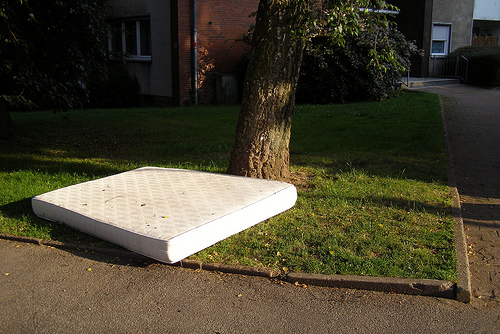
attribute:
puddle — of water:
[404, 50, 461, 95]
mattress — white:
[24, 159, 299, 269]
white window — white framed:
[427, 20, 452, 60]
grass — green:
[265, 218, 312, 256]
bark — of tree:
[227, 1, 315, 184]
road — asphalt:
[1, 230, 499, 328]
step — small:
[407, 76, 453, 87]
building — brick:
[5, 3, 350, 126]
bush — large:
[303, 9, 435, 94]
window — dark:
[115, 11, 159, 66]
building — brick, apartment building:
[15, 0, 477, 101]